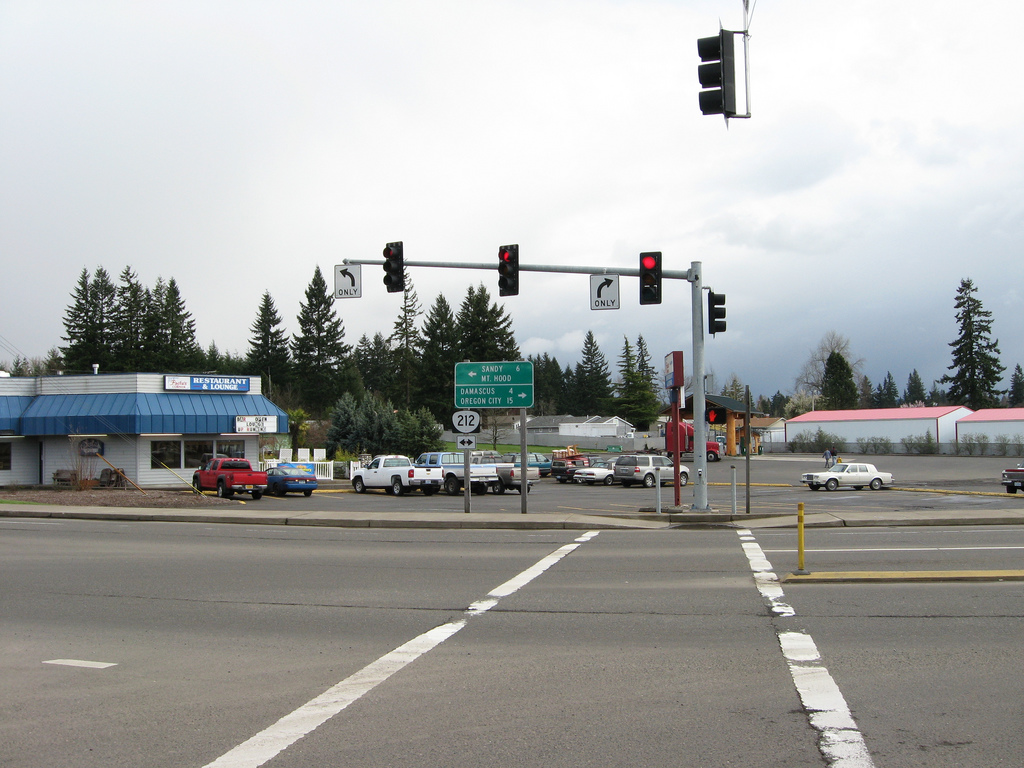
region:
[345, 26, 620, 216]
grey and white sky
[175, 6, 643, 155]
white clouds in sky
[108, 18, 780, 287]
thick clouds in sky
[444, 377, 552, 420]
green and white sign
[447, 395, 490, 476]
black and white road sign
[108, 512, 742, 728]
white crosswalk on road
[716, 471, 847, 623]
yellow marker on road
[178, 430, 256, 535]
red truck is parked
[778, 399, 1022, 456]
white buildings with pink roofs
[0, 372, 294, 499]
restaurant with blue awnings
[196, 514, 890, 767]
crosswalk at street intersection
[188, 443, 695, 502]
cars parked in lot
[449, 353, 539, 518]
street sign and highway sign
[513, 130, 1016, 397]
billowing white clouds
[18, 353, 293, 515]
blue and white building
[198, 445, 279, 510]
parked red truck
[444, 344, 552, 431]
green and white street sign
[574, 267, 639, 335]
black and white street sign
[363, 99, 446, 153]
white clouds in blue sky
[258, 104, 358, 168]
white clouds in blue sky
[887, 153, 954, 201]
white clouds in blue sky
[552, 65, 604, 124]
white clouds in blue sky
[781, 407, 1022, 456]
two white buildings with pink roofs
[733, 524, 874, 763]
painted white line is broken in places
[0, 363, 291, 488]
white building with blue awning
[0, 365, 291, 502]
red pickup truck parked in front of building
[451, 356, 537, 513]
green and white street sign on two posts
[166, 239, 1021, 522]
traffic lights in front of a parking lot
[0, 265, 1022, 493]
tall trees, primarily pine, behind buildings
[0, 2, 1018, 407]
sky appears full of grey clouds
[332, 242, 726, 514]
visible traffic lights are signalling red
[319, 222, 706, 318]
a red traffic light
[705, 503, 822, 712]
a white painted line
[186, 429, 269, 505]
a red pickup truck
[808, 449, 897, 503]
a white car on lot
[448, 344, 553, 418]
a green and white road sign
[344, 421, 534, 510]
three trucks parked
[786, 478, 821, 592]
a yell pole on the media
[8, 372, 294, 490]
a blue and white building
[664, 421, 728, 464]
a red semi truck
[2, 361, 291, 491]
restaurant painted blue and white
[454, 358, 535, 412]
a green traffic sign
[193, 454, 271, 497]
a parked red pickup truck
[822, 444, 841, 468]
two people walking toward the semi truck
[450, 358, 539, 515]
green direction sign for different locations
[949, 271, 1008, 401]
tall evergreen treen behind a building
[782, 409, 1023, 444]
white pole barns with red roofs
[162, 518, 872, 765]
a worn crosswalk in the street